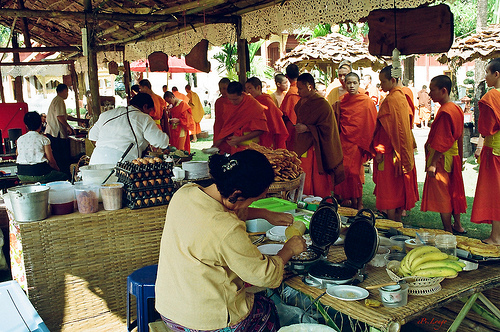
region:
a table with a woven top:
[244, 202, 499, 328]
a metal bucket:
[1, 178, 51, 223]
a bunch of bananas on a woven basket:
[387, 239, 464, 297]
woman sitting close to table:
[155, 149, 497, 329]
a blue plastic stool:
[123, 259, 157, 329]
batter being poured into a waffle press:
[267, 199, 341, 264]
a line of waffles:
[323, 198, 498, 270]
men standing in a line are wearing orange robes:
[204, 62, 499, 244]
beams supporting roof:
[5, 2, 250, 124]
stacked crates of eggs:
[115, 153, 172, 208]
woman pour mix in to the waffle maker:
[283, 236, 311, 263]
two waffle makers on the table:
[293, 205, 367, 282]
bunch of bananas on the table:
[400, 231, 462, 284]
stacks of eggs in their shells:
[127, 151, 169, 217]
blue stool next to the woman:
[123, 257, 174, 315]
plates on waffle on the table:
[386, 207, 492, 260]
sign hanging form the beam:
[353, 1, 468, 62]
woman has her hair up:
[206, 145, 253, 181]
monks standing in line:
[210, 73, 302, 139]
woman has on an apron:
[97, 106, 137, 128]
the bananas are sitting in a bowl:
[387, 245, 461, 287]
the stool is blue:
[126, 266, 156, 304]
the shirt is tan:
[174, 216, 201, 262]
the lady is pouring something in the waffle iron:
[272, 210, 339, 269]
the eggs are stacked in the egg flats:
[131, 152, 168, 202]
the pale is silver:
[8, 177, 48, 220]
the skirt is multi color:
[254, 305, 269, 327]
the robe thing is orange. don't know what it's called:
[345, 102, 364, 132]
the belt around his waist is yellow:
[448, 144, 459, 161]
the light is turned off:
[382, 40, 412, 84]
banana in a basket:
[386, 241, 468, 288]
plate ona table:
[318, 277, 380, 307]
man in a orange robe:
[376, 83, 422, 206]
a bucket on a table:
[7, 177, 49, 224]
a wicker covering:
[37, 215, 148, 280]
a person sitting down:
[16, 112, 65, 184]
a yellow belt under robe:
[442, 131, 462, 181]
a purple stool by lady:
[122, 259, 177, 324]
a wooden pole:
[83, 16, 100, 111]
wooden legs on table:
[442, 296, 496, 328]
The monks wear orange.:
[306, 88, 496, 195]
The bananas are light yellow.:
[399, 243, 462, 280]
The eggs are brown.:
[122, 159, 175, 204]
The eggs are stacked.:
[117, 156, 175, 207]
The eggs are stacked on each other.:
[118, 154, 175, 208]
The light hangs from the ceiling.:
[391, 0, 403, 80]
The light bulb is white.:
[389, 45, 401, 77]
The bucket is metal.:
[6, 183, 50, 223]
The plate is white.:
[325, 281, 372, 301]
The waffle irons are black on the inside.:
[288, 196, 383, 284]